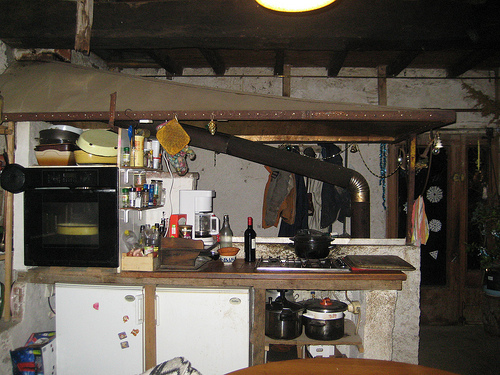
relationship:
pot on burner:
[286, 222, 338, 260] [270, 244, 350, 278]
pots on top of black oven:
[264, 294, 306, 340] [23, 168, 118, 268]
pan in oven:
[56, 221, 100, 237] [15, 162, 137, 262]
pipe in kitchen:
[165, 116, 389, 209] [0, 1, 492, 357]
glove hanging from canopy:
[164, 142, 198, 177] [0, 53, 461, 132]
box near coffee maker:
[168, 212, 187, 237] [178, 188, 220, 244]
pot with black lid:
[287, 227, 335, 260] [289, 223, 335, 244]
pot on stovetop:
[287, 227, 335, 260] [258, 245, 350, 275]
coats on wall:
[261, 143, 355, 235] [159, 140, 386, 241]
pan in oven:
[56, 221, 100, 237] [14, 142, 151, 270]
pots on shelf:
[256, 284, 355, 359] [261, 316, 359, 348]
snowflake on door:
[421, 182, 452, 206] [393, 132, 480, 325]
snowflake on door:
[428, 217, 442, 234] [393, 132, 480, 325]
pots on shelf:
[264, 294, 306, 340] [24, 163, 116, 170]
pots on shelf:
[302, 290, 347, 341] [267, 338, 367, 345]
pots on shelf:
[74, 128, 118, 162] [24, 163, 116, 170]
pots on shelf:
[34, 123, 78, 164] [24, 163, 116, 170]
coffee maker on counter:
[170, 188, 220, 242] [18, 249, 407, 290]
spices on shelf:
[122, 180, 162, 210] [123, 159, 165, 244]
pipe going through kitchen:
[114, 119, 370, 238] [0, 1, 492, 357]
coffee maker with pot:
[168, 169, 220, 251] [196, 211, 221, 241]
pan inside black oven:
[53, 219, 100, 239] [23, 168, 118, 268]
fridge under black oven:
[55, 283, 144, 373] [23, 168, 118, 268]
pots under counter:
[264, 294, 306, 340] [15, 258, 404, 295]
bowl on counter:
[217, 245, 240, 265] [15, 258, 404, 295]